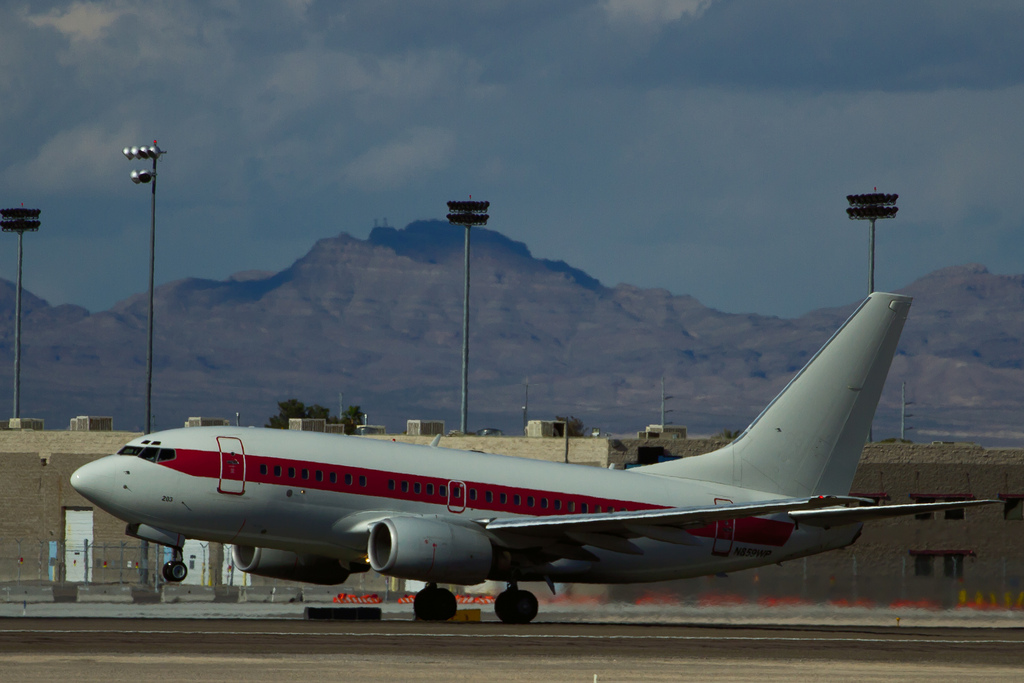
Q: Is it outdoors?
A: Yes, it is outdoors.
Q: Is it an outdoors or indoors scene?
A: It is outdoors.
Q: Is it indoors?
A: No, it is outdoors.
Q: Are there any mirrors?
A: No, there are no mirrors.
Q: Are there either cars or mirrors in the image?
A: No, there are no mirrors or cars.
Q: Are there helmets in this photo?
A: No, there are no helmets.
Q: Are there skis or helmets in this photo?
A: No, there are no helmets or skis.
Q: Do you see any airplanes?
A: Yes, there is an airplane.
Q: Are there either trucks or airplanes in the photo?
A: Yes, there is an airplane.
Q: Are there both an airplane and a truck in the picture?
A: No, there is an airplane but no trucks.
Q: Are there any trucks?
A: No, there are no trucks.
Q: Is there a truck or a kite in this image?
A: No, there are no trucks or kites.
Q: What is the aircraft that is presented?
A: The aircraft is an airplane.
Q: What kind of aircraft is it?
A: The aircraft is an airplane.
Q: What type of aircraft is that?
A: This is an airplane.